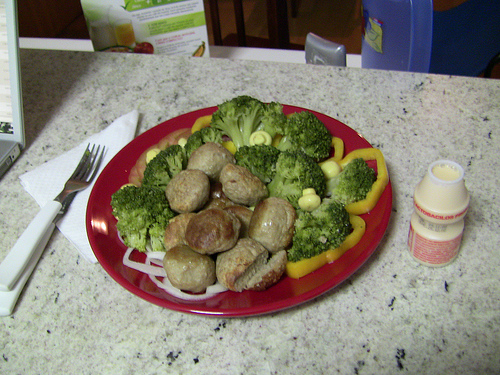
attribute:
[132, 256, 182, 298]
slices — thin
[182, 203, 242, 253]
meat ball — brown, colored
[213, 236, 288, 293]
meat ball — colored, brown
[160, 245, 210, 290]
meat ball — brown, colored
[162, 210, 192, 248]
meat ball — colored, brown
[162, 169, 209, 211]
meat ball — brown, colored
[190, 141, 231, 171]
meat ball — colored, brown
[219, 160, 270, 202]
meat ball — brown, colored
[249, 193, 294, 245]
meat ball — colored, brown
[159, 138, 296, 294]
meat balls — brown, colored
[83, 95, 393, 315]
plate — red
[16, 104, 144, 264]
napkin — white, triangular, folder, paper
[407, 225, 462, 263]
writing — red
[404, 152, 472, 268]
drink — little, small, probiotic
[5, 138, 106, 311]
utensils — white, handled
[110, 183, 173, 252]
crown — green, broccoli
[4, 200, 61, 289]
handle — plastic, white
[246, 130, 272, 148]
mushroom — little, off white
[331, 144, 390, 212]
bellpepper — sliced, cooked, yellow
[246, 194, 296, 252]
meatball — cooked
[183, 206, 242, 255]
meatball — brown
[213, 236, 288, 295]
meatball — cut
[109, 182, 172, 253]
broccoli — green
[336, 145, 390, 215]
bell pepper — yellow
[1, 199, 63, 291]
handle — white